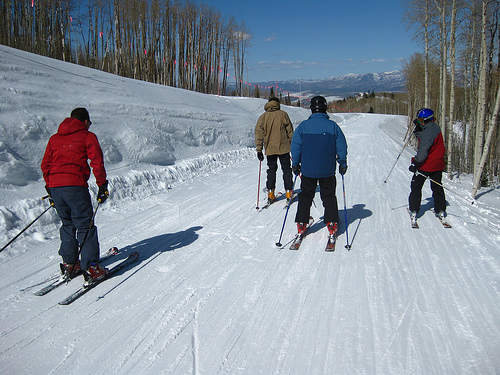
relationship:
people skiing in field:
[25, 90, 456, 304] [4, 115, 500, 367]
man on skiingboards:
[38, 101, 112, 281] [35, 240, 139, 307]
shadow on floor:
[89, 217, 208, 287] [4, 110, 497, 372]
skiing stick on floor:
[273, 171, 300, 252] [4, 110, 497, 372]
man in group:
[41, 107, 108, 282] [10, 86, 463, 313]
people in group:
[290, 95, 348, 234] [10, 86, 463, 313]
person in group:
[243, 94, 300, 212] [10, 86, 463, 313]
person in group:
[379, 104, 498, 228] [10, 86, 463, 313]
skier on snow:
[6, 104, 139, 309] [1, 44, 500, 371]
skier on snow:
[243, 94, 300, 212] [247, 89, 297, 210]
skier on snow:
[272, 92, 360, 254] [1, 44, 500, 371]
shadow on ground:
[89, 217, 208, 287] [3, 44, 500, 364]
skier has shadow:
[6, 104, 139, 309] [89, 217, 208, 287]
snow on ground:
[1, 44, 500, 371] [3, 44, 500, 364]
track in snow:
[125, 214, 270, 374] [1, 44, 500, 371]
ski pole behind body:
[65, 200, 104, 289] [38, 127, 101, 268]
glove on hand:
[96, 178, 110, 207] [96, 183, 112, 204]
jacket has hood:
[35, 116, 109, 192] [55, 115, 86, 138]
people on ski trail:
[25, 90, 456, 304] [4, 109, 499, 367]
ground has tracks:
[3, 44, 500, 364] [5, 111, 498, 372]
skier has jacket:
[6, 104, 139, 309] [35, 116, 109, 192]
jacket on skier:
[35, 116, 109, 192] [6, 104, 139, 309]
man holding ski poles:
[41, 107, 108, 282] [1, 188, 106, 292]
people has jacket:
[290, 95, 348, 234] [289, 110, 350, 185]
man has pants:
[41, 107, 108, 282] [44, 183, 100, 263]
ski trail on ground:
[4, 109, 499, 367] [3, 44, 500, 364]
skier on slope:
[6, 104, 139, 309] [4, 40, 500, 368]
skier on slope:
[272, 92, 360, 254] [4, 40, 500, 368]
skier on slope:
[247, 89, 297, 210] [4, 40, 500, 368]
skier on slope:
[382, 105, 466, 232] [4, 40, 500, 368]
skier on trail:
[6, 104, 139, 309] [5, 107, 499, 372]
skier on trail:
[272, 92, 360, 254] [5, 107, 499, 372]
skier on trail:
[382, 105, 466, 232] [5, 107, 499, 372]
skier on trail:
[251, 93, 304, 208] [5, 107, 499, 372]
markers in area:
[0, 0, 303, 96] [4, 0, 354, 212]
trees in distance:
[247, 82, 410, 111] [233, 9, 500, 156]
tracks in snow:
[5, 111, 498, 372] [1, 44, 500, 371]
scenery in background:
[6, 2, 498, 107] [0, 6, 499, 209]